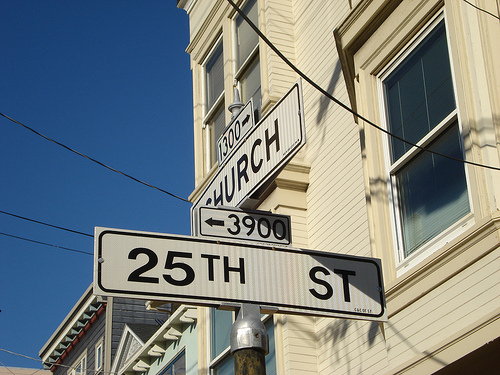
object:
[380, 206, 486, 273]
trim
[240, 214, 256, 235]
number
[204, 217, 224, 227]
arrow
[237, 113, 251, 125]
arrow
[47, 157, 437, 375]
metal holder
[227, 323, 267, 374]
pole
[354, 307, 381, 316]
numbers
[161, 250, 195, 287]
numbers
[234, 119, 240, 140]
numbers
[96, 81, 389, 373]
sign whole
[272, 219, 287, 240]
number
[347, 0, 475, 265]
window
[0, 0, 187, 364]
sky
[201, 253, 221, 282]
letter t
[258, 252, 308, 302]
grey lines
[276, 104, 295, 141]
grey lines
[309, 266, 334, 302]
letter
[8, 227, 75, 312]
clouds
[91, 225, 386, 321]
address sign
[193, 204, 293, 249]
address sign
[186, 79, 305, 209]
address sign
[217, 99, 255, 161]
address sign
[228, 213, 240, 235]
number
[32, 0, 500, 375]
building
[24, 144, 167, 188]
line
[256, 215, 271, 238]
number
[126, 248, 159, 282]
number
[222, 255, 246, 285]
letter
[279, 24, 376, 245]
siding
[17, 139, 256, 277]
background